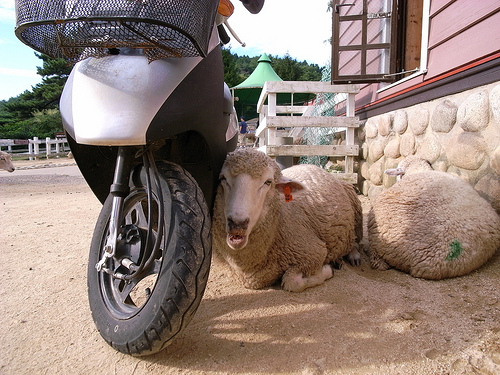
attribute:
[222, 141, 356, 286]
lamb — resting, sleepy, forward, off-white, woolen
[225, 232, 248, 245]
mouth — open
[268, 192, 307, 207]
tag — red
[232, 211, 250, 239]
nose — black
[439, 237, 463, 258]
stain — green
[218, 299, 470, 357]
ground — sandy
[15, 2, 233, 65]
basket — metal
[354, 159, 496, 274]
sheep — facing away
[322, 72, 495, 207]
wall — stone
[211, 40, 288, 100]
umbrella — green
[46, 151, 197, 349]
tire — black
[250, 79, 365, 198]
fence — homemade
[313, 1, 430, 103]
window — open